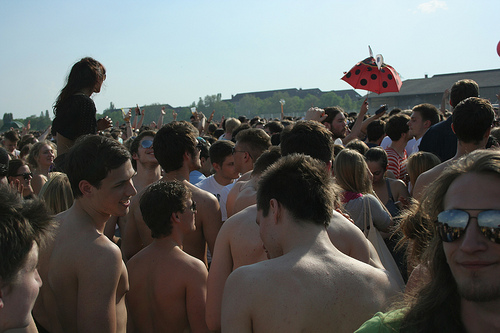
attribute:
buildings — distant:
[208, 70, 344, 116]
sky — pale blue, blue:
[0, 0, 499, 120]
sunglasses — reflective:
[435, 207, 499, 249]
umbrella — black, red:
[343, 55, 400, 100]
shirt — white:
[193, 173, 243, 262]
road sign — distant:
[272, 90, 290, 121]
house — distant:
[363, 67, 498, 112]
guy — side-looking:
[32, 129, 159, 329]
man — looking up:
[111, 126, 172, 258]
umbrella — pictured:
[340, 44, 405, 101]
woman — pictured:
[38, 55, 122, 149]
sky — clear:
[115, 24, 251, 81]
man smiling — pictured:
[361, 147, 498, 327]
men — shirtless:
[44, 133, 388, 325]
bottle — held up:
[134, 105, 142, 118]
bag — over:
[320, 148, 388, 198]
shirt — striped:
[383, 144, 413, 185]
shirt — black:
[46, 89, 100, 142]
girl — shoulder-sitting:
[44, 53, 118, 148]